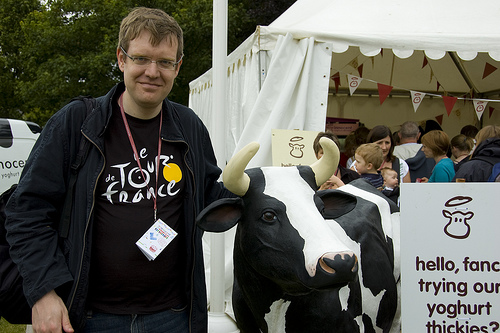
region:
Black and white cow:
[201, 137, 404, 328]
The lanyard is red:
[115, 91, 172, 229]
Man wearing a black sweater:
[23, 10, 235, 330]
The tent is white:
[191, 0, 491, 322]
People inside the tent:
[336, 89, 496, 194]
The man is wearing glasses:
[108, 12, 196, 103]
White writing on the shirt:
[103, 144, 190, 216]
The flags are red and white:
[329, 62, 498, 119]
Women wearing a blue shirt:
[416, 128, 464, 188]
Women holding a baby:
[357, 128, 411, 195]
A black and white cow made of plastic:
[224, 148, 387, 332]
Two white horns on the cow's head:
[216, 134, 349, 201]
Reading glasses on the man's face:
[119, 46, 181, 76]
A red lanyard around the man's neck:
[108, 83, 186, 254]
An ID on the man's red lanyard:
[129, 216, 178, 267]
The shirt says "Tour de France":
[92, 136, 189, 206]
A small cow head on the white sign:
[264, 124, 331, 176]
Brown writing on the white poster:
[414, 258, 499, 332]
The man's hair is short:
[122, 7, 185, 57]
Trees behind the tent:
[5, 0, 233, 102]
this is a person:
[14, 13, 234, 327]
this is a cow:
[206, 105, 374, 332]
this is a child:
[349, 140, 389, 193]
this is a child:
[368, 163, 404, 199]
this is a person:
[349, 113, 416, 211]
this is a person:
[413, 127, 456, 195]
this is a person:
[462, 127, 498, 182]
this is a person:
[392, 114, 422, 152]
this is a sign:
[401, 187, 498, 332]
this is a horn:
[294, 127, 355, 203]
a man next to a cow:
[103, 36, 358, 306]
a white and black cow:
[231, 137, 392, 319]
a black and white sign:
[405, 185, 495, 330]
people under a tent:
[348, 109, 495, 187]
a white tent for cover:
[236, 38, 328, 130]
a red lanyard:
[118, 102, 170, 217]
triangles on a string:
[348, 72, 489, 125]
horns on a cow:
[218, 137, 353, 185]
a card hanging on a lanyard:
[127, 208, 178, 280]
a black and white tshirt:
[92, 93, 199, 321]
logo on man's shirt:
[100, 148, 180, 207]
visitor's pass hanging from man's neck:
[132, 216, 179, 261]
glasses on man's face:
[115, 45, 183, 70]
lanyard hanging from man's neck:
[117, 91, 163, 218]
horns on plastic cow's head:
[222, 142, 339, 194]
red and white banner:
[330, 72, 499, 122]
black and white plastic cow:
[192, 135, 398, 331]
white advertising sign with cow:
[399, 183, 499, 331]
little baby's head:
[382, 168, 398, 188]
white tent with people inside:
[188, 0, 498, 332]